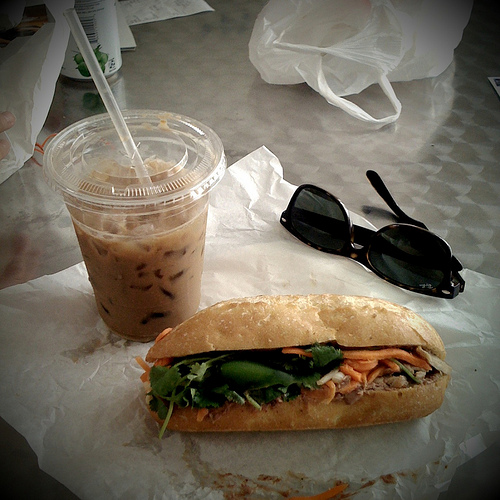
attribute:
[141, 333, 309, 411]
vegetable — dark, leafy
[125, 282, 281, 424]
end — one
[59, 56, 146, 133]
straw — plastic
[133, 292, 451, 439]
sandwich — maked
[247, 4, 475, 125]
plastic bag — empty, white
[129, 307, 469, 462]
sandwich — small, sub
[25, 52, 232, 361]
cup — plastic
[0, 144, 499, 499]
waxed paper — white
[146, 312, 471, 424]
carrots — orange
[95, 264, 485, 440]
sandwich — in a roll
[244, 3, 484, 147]
bag — plastic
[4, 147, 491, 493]
paper — wax, white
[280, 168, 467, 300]
sunglasses — black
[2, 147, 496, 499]
wax paper — white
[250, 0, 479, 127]
bag — reflection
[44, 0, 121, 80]
aluminum can — green, white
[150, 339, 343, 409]
lettuce — green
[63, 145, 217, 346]
coffee — iced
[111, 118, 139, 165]
straw — clear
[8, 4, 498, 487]
table — beige, patterned